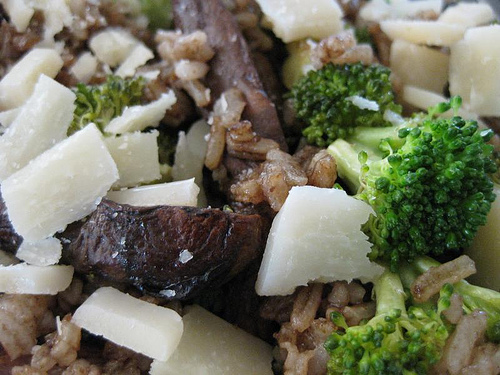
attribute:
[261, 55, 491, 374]
broccoli — green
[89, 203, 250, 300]
beef — cooked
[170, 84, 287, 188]
rice — cooked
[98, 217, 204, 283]
mushroom top — brown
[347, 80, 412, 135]
flecks — white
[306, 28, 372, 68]
rice — white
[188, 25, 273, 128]
meat — beef, brown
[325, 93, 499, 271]
broccoli piece — green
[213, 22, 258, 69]
meat — cooked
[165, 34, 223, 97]
rice — brown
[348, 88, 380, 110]
chunk — white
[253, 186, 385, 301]
vegetable — white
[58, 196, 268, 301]
meat — brown, cooked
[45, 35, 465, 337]
mixed vegetables — bunch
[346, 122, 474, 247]
vegetable — green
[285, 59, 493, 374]
broccoli — green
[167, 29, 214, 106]
rice — brown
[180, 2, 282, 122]
meat — brown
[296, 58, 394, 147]
broccolli — green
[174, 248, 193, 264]
spot — white